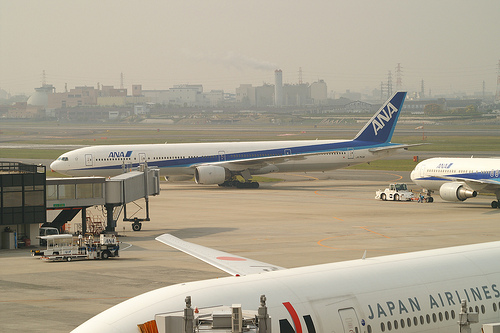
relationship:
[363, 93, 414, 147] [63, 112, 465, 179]
tail of a plane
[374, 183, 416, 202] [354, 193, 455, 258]
toad truck on concrete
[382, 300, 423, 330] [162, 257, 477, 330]
windows of a plane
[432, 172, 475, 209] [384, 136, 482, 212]
engine of a plane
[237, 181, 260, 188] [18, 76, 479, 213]
landing gears on a platform